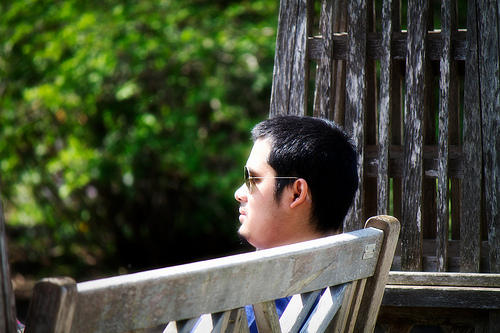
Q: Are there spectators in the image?
A: No, there are no spectators.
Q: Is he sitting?
A: Yes, the man is sitting.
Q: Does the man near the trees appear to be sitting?
A: Yes, the man is sitting.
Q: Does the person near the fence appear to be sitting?
A: Yes, the man is sitting.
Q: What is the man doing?
A: The man is sitting.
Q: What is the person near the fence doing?
A: The man is sitting.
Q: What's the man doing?
A: The man is sitting.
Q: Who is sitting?
A: The man is sitting.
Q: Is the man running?
A: No, the man is sitting.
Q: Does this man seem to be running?
A: No, the man is sitting.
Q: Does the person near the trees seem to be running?
A: No, the man is sitting.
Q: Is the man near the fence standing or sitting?
A: The man is sitting.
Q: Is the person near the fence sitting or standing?
A: The man is sitting.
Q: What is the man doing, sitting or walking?
A: The man is sitting.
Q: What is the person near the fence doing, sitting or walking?
A: The man is sitting.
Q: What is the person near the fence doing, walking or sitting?
A: The man is sitting.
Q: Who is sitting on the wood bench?
A: The man is sitting on the bench.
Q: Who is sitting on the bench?
A: The man is sitting on the bench.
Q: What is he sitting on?
A: The man is sitting on the bench.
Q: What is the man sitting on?
A: The man is sitting on the bench.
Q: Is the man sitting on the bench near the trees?
A: Yes, the man is sitting on the bench.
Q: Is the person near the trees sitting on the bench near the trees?
A: Yes, the man is sitting on the bench.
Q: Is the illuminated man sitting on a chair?
A: No, the man is sitting on the bench.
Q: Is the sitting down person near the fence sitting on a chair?
A: No, the man is sitting on the bench.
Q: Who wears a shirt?
A: The man wears a shirt.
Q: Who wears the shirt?
A: The man wears a shirt.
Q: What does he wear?
A: The man wears a shirt.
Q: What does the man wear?
A: The man wears a shirt.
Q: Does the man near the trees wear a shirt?
A: Yes, the man wears a shirt.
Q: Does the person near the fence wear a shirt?
A: Yes, the man wears a shirt.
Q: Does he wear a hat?
A: No, the man wears a shirt.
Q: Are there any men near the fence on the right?
A: Yes, there is a man near the fence.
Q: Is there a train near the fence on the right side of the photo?
A: No, there is a man near the fence.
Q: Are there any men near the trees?
A: Yes, there is a man near the trees.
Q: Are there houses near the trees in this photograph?
A: No, there is a man near the trees.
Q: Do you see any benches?
A: Yes, there is a bench.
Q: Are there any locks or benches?
A: Yes, there is a bench.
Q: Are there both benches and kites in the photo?
A: No, there is a bench but no kites.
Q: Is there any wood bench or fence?
A: Yes, there is a wood bench.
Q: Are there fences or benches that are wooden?
A: Yes, the bench is wooden.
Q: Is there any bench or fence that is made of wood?
A: Yes, the bench is made of wood.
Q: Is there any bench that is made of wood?
A: Yes, there is a bench that is made of wood.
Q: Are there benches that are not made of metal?
A: Yes, there is a bench that is made of wood.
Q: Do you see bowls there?
A: No, there are no bowls.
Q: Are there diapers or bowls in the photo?
A: No, there are no bowls or diapers.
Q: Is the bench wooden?
A: Yes, the bench is wooden.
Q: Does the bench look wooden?
A: Yes, the bench is wooden.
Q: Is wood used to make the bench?
A: Yes, the bench is made of wood.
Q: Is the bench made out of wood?
A: Yes, the bench is made of wood.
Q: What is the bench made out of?
A: The bench is made of wood.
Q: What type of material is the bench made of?
A: The bench is made of wood.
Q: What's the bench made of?
A: The bench is made of wood.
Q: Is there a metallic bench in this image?
A: No, there is a bench but it is wooden.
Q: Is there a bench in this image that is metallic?
A: No, there is a bench but it is wooden.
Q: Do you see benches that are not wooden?
A: No, there is a bench but it is wooden.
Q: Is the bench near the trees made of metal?
A: No, the bench is made of wood.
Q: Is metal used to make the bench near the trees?
A: No, the bench is made of wood.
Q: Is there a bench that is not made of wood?
A: No, there is a bench but it is made of wood.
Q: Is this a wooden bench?
A: Yes, this is a wooden bench.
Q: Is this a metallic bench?
A: No, this is a wooden bench.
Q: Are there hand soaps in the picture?
A: No, there are no hand soaps.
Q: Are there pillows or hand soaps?
A: No, there are no hand soaps or pillows.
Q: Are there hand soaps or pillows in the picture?
A: No, there are no hand soaps or pillows.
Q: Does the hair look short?
A: Yes, the hair is short.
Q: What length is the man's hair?
A: The hair is short.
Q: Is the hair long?
A: No, the hair is short.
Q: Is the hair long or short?
A: The hair is short.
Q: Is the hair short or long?
A: The hair is short.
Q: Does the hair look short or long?
A: The hair is short.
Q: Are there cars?
A: No, there are no cars.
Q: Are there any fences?
A: Yes, there is a fence.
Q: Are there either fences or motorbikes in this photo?
A: Yes, there is a fence.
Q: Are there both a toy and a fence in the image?
A: No, there is a fence but no toys.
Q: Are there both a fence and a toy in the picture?
A: No, there is a fence but no toys.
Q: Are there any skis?
A: No, there are no skis.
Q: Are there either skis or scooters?
A: No, there are no skis or scooters.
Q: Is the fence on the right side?
A: Yes, the fence is on the right of the image.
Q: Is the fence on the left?
A: No, the fence is on the right of the image.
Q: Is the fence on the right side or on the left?
A: The fence is on the right of the image.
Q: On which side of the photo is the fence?
A: The fence is on the right of the image.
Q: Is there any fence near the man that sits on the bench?
A: Yes, there is a fence near the man.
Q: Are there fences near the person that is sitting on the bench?
A: Yes, there is a fence near the man.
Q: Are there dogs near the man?
A: No, there is a fence near the man.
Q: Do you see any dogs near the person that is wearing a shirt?
A: No, there is a fence near the man.